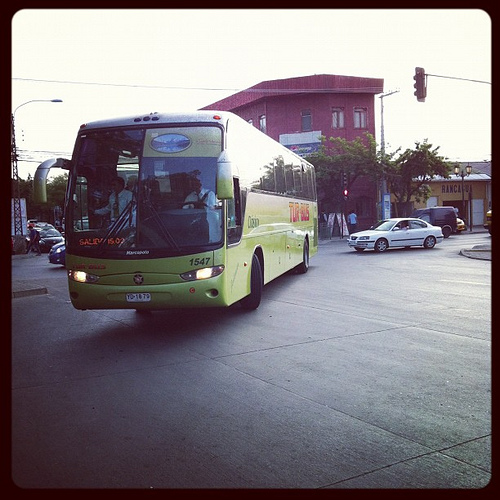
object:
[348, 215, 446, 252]
car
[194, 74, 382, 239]
building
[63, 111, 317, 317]
bus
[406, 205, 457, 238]
suv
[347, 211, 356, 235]
man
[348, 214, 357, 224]
shirt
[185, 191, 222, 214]
shirt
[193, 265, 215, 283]
headlight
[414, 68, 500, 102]
traffic light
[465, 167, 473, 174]
light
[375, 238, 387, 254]
wheel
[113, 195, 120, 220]
tie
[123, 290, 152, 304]
licence plate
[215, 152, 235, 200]
mirror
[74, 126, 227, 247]
windshield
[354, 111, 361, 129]
windows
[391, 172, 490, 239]
building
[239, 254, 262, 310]
tire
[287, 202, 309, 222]
letters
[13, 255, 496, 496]
road